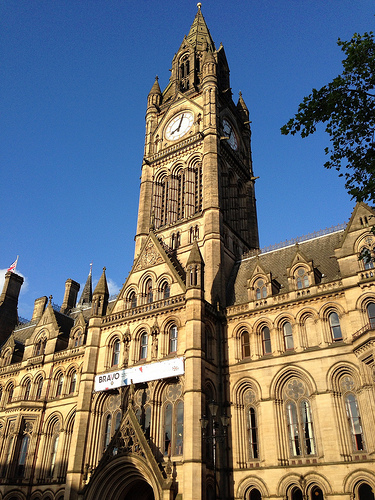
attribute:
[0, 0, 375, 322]
sky — blue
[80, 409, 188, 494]
entrance — darkened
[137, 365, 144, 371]
triangles — black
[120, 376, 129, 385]
triangles — red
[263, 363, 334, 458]
curtains — white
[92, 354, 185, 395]
board — white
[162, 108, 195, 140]
clock — white, black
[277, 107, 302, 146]
ground — stone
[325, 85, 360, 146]
leaves — green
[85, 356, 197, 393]
sign — white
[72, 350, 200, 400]
sign — white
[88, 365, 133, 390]
letters — black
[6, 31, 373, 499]
building — tan, stone, brown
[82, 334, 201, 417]
banner — white